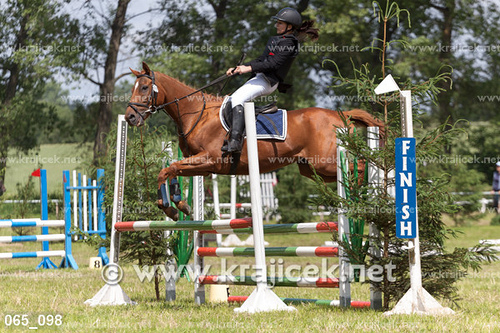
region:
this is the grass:
[28, 282, 54, 297]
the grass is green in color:
[37, 280, 77, 305]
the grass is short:
[21, 279, 65, 306]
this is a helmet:
[276, 4, 300, 25]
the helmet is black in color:
[278, 7, 294, 19]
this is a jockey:
[223, 2, 303, 160]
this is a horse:
[115, 66, 411, 215]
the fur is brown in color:
[308, 108, 323, 140]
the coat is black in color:
[276, 45, 288, 65]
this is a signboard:
[393, 139, 418, 242]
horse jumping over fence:
[87, 8, 398, 309]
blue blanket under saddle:
[253, 101, 290, 151]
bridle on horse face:
[129, 82, 160, 124]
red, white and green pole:
[282, 220, 333, 261]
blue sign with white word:
[384, 136, 419, 258]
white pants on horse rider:
[224, 64, 286, 134]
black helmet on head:
[270, 5, 307, 29]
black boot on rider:
[221, 98, 246, 159]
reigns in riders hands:
[199, 63, 248, 94]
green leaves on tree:
[9, 25, 88, 172]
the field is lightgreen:
[112, 282, 163, 320]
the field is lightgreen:
[136, 300, 218, 311]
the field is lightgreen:
[89, 284, 183, 322]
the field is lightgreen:
[6, 272, 78, 320]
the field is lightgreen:
[16, 252, 111, 306]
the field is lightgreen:
[86, 274, 131, 331]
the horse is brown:
[83, 26, 403, 246]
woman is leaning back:
[200, 10, 316, 196]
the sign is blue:
[386, 80, 432, 240]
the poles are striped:
[125, 182, 381, 302]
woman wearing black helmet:
[262, 0, 342, 60]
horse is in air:
[111, 38, 383, 219]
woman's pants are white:
[211, 60, 311, 134]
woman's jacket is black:
[225, 21, 319, 103]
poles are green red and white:
[87, 192, 378, 296]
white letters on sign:
[388, 114, 429, 249]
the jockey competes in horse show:
[14, 11, 476, 286]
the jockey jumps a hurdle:
[71, 13, 447, 315]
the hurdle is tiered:
[60, 77, 452, 317]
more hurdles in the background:
[3, 142, 106, 282]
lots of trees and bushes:
[13, 11, 479, 261]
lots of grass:
[6, 219, 488, 329]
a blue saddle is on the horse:
[117, 57, 409, 154]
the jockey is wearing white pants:
[217, 3, 312, 180]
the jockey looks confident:
[98, 3, 299, 223]